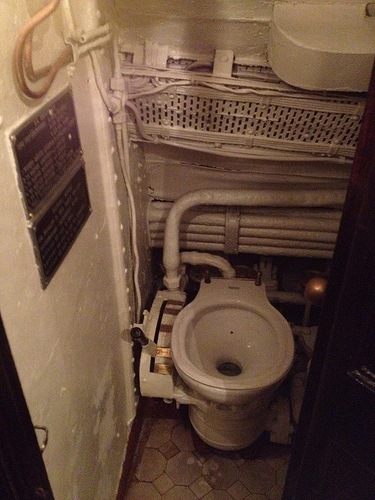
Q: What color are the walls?
A: White.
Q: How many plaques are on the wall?
A: Two.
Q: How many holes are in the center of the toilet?
A: One.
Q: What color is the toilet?
A: White.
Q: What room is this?
A: Bathroom.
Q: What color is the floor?
A: Brown.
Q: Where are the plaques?
A: On the left wall.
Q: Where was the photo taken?
A: In a bathroom also used for utility.